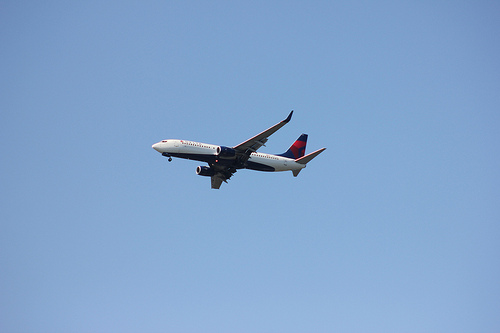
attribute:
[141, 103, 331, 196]
plane — white, flying, large, blue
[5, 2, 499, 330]
sky — blue, clear, sunny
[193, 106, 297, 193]
wings — grey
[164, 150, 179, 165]
landing gear — up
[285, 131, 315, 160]
tail — red, blue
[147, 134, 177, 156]
cockpit — white